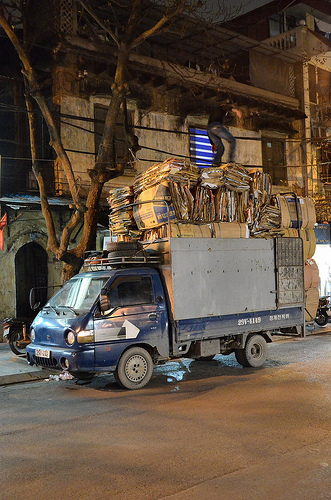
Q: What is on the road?
A: A truck.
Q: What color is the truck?
A: Blue.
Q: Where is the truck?
A: On the street.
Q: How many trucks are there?
A: One.